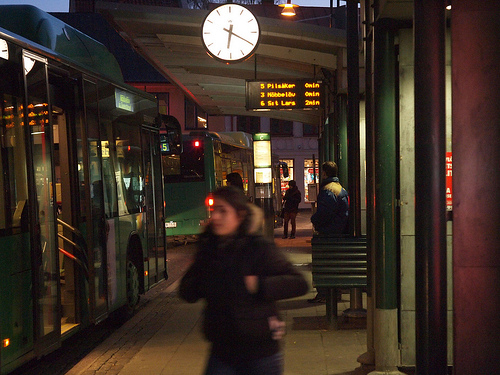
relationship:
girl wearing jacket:
[177, 189, 310, 374] [174, 228, 309, 342]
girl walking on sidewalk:
[177, 189, 310, 374] [72, 244, 371, 371]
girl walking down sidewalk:
[182, 189, 316, 372] [72, 244, 371, 371]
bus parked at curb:
[137, 97, 271, 237] [77, 245, 215, 367]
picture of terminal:
[3, 2, 485, 372] [8, 4, 498, 371]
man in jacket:
[309, 155, 357, 235] [307, 178, 357, 230]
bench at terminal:
[308, 224, 370, 326] [8, 4, 498, 371]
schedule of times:
[245, 75, 335, 116] [254, 80, 326, 107]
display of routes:
[249, 123, 279, 210] [252, 133, 276, 188]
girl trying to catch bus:
[177, 189, 310, 374] [1, 1, 182, 372]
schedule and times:
[245, 75, 335, 125] [254, 82, 330, 111]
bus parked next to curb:
[1, 1, 182, 372] [59, 203, 194, 373]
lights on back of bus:
[184, 135, 216, 217] [153, 127, 253, 237]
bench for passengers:
[308, 224, 363, 321] [163, 155, 363, 372]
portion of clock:
[205, 46, 246, 72] [195, 5, 265, 70]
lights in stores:
[276, 155, 320, 187] [272, 138, 329, 218]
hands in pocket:
[188, 266, 268, 306] [196, 265, 260, 299]